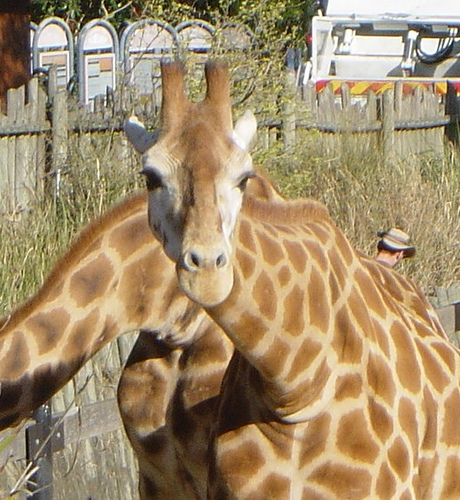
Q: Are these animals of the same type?
A: Yes, all the animals are giraffes.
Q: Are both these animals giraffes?
A: Yes, all the animals are giraffes.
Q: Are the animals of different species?
A: No, all the animals are giraffes.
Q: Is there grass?
A: Yes, there is grass.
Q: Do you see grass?
A: Yes, there is grass.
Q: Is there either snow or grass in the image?
A: Yes, there is grass.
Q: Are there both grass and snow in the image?
A: No, there is grass but no snow.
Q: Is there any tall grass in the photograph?
A: Yes, there is tall grass.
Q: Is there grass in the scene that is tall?
A: Yes, there is grass that is tall.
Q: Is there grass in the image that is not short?
A: Yes, there is tall grass.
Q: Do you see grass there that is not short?
A: Yes, there is tall grass.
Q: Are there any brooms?
A: No, there are no brooms.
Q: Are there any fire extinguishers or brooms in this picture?
A: No, there are no brooms or fire extinguishers.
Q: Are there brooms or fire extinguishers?
A: No, there are no brooms or fire extinguishers.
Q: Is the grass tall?
A: Yes, the grass is tall.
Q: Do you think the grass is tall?
A: Yes, the grass is tall.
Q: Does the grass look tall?
A: Yes, the grass is tall.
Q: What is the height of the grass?
A: The grass is tall.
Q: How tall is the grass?
A: The grass is tall.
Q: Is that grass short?
A: No, the grass is tall.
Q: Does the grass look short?
A: No, the grass is tall.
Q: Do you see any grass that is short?
A: No, there is grass but it is tall.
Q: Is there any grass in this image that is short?
A: No, there is grass but it is tall.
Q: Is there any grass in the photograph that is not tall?
A: No, there is grass but it is tall.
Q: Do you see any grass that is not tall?
A: No, there is grass but it is tall.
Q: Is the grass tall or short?
A: The grass is tall.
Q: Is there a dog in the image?
A: No, there are no dogs.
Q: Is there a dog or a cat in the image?
A: No, there are no dogs or cats.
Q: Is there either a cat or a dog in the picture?
A: No, there are no dogs or cats.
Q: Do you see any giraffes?
A: Yes, there is a giraffe.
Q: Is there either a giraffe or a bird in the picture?
A: Yes, there is a giraffe.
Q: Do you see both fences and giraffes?
A: Yes, there are both a giraffe and a fence.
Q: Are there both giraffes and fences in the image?
A: Yes, there are both a giraffe and a fence.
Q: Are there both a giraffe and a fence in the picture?
A: Yes, there are both a giraffe and a fence.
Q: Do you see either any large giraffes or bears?
A: Yes, there is a large giraffe.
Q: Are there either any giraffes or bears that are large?
A: Yes, the giraffe is large.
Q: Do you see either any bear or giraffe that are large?
A: Yes, the giraffe is large.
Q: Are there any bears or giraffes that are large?
A: Yes, the giraffe is large.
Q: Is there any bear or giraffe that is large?
A: Yes, the giraffe is large.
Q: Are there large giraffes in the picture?
A: Yes, there is a large giraffe.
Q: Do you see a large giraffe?
A: Yes, there is a large giraffe.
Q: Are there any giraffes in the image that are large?
A: Yes, there is a giraffe that is large.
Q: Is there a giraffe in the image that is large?
A: Yes, there is a giraffe that is large.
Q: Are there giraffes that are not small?
A: Yes, there is a large giraffe.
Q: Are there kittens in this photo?
A: No, there are no kittens.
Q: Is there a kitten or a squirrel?
A: No, there are no kittens or squirrels.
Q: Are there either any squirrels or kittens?
A: No, there are no kittens or squirrels.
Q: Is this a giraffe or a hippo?
A: This is a giraffe.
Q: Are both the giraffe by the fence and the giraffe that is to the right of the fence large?
A: Yes, both the giraffe and the giraffe are large.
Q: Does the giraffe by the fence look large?
A: Yes, the giraffe is large.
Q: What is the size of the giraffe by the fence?
A: The giraffe is large.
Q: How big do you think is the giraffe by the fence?
A: The giraffe is large.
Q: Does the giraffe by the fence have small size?
A: No, the giraffe is large.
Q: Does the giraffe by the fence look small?
A: No, the giraffe is large.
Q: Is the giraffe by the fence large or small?
A: The giraffe is large.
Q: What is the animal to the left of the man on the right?
A: The animal is a giraffe.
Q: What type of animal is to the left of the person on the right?
A: The animal is a giraffe.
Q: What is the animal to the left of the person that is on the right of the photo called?
A: The animal is a giraffe.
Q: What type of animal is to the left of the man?
A: The animal is a giraffe.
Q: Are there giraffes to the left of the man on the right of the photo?
A: Yes, there is a giraffe to the left of the man.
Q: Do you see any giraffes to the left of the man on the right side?
A: Yes, there is a giraffe to the left of the man.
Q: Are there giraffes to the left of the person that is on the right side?
A: Yes, there is a giraffe to the left of the man.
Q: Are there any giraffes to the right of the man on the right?
A: No, the giraffe is to the left of the man.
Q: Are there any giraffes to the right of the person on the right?
A: No, the giraffe is to the left of the man.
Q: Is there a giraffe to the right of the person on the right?
A: No, the giraffe is to the left of the man.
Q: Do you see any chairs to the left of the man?
A: No, there is a giraffe to the left of the man.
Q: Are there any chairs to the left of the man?
A: No, there is a giraffe to the left of the man.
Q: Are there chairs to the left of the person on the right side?
A: No, there is a giraffe to the left of the man.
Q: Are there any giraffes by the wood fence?
A: Yes, there is a giraffe by the fence.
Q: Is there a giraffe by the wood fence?
A: Yes, there is a giraffe by the fence.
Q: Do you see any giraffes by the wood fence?
A: Yes, there is a giraffe by the fence.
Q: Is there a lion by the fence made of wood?
A: No, there is a giraffe by the fence.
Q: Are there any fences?
A: Yes, there is a fence.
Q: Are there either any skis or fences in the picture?
A: Yes, there is a fence.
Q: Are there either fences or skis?
A: Yes, there is a fence.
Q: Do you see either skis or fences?
A: Yes, there is a fence.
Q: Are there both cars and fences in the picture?
A: No, there is a fence but no cars.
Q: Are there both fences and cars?
A: No, there is a fence but no cars.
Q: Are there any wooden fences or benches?
A: Yes, there is a wood fence.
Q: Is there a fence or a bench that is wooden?
A: Yes, the fence is wooden.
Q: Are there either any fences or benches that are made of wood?
A: Yes, the fence is made of wood.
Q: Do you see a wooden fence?
A: Yes, there is a wood fence.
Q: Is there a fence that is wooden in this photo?
A: Yes, there is a wood fence.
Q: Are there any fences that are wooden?
A: Yes, there is a fence that is wooden.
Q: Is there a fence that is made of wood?
A: Yes, there is a fence that is made of wood.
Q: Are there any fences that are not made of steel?
A: Yes, there is a fence that is made of wood.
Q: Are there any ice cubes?
A: No, there are no ice cubes.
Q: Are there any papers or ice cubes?
A: No, there are no ice cubes or papers.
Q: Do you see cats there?
A: No, there are no cats.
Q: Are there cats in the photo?
A: No, there are no cats.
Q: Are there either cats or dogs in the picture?
A: No, there are no cats or dogs.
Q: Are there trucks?
A: Yes, there is a truck.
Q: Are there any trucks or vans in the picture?
A: Yes, there is a truck.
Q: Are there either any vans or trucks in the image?
A: Yes, there is a truck.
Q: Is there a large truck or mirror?
A: Yes, there is a large truck.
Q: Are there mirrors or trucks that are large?
A: Yes, the truck is large.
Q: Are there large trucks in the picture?
A: Yes, there is a large truck.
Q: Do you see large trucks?
A: Yes, there is a large truck.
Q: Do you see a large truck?
A: Yes, there is a large truck.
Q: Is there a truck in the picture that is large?
A: Yes, there is a truck that is large.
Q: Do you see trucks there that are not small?
A: Yes, there is a large truck.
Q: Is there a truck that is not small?
A: Yes, there is a large truck.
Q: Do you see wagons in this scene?
A: No, there are no wagons.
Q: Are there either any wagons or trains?
A: No, there are no wagons or trains.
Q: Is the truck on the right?
A: Yes, the truck is on the right of the image.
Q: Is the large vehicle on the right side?
A: Yes, the truck is on the right of the image.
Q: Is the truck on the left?
A: No, the truck is on the right of the image.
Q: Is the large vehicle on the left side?
A: No, the truck is on the right of the image.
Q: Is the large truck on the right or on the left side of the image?
A: The truck is on the right of the image.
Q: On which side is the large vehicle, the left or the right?
A: The truck is on the right of the image.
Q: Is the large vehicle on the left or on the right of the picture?
A: The truck is on the right of the image.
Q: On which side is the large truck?
A: The truck is on the right of the image.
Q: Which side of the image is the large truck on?
A: The truck is on the right of the image.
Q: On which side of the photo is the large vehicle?
A: The truck is on the right of the image.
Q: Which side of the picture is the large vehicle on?
A: The truck is on the right of the image.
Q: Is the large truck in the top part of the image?
A: Yes, the truck is in the top of the image.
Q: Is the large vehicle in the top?
A: Yes, the truck is in the top of the image.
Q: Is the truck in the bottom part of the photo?
A: No, the truck is in the top of the image.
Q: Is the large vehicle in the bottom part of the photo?
A: No, the truck is in the top of the image.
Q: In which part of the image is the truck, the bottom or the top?
A: The truck is in the top of the image.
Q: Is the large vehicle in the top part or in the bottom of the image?
A: The truck is in the top of the image.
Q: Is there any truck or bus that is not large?
A: No, there is a truck but it is large.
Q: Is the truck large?
A: Yes, the truck is large.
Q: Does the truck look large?
A: Yes, the truck is large.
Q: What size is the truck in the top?
A: The truck is large.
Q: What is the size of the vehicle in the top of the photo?
A: The truck is large.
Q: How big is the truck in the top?
A: The truck is large.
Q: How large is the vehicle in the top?
A: The truck is large.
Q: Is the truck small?
A: No, the truck is large.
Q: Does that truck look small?
A: No, the truck is large.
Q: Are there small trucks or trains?
A: No, there is a truck but it is large.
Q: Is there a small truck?
A: No, there is a truck but it is large.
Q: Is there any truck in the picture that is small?
A: No, there is a truck but it is large.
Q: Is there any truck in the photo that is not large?
A: No, there is a truck but it is large.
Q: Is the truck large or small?
A: The truck is large.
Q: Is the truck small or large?
A: The truck is large.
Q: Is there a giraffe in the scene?
A: Yes, there is a giraffe.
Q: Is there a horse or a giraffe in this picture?
A: Yes, there is a giraffe.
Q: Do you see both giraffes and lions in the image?
A: No, there is a giraffe but no lions.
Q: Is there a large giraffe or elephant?
A: Yes, there is a large giraffe.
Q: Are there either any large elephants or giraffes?
A: Yes, there is a large giraffe.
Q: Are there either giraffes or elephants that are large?
A: Yes, the giraffe is large.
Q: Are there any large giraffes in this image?
A: Yes, there is a large giraffe.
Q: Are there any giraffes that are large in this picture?
A: Yes, there is a large giraffe.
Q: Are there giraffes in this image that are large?
A: Yes, there is a large giraffe.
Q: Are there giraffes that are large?
A: Yes, there is a giraffe that is large.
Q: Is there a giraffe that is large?
A: Yes, there is a giraffe that is large.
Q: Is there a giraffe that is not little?
A: Yes, there is a large giraffe.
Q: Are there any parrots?
A: No, there are no parrots.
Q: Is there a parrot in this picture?
A: No, there are no parrots.